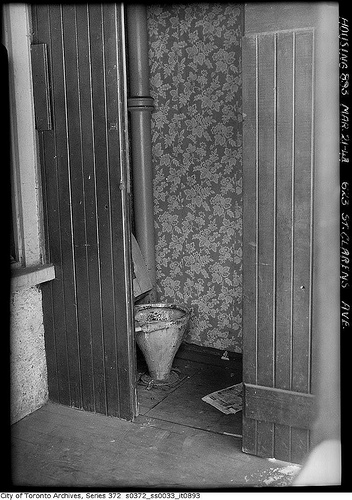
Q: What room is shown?
A: A bathroom.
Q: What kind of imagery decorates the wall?
A: Floral print.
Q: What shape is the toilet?
A: Conical.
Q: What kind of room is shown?
A: A bathroom.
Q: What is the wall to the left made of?
A: Wood.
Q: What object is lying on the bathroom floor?
A: A piece of paper.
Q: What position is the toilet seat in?
A: It is up.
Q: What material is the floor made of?
A: Wood.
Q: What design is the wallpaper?
A: Floral.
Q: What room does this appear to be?
A: Bathroom.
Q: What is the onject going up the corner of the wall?
A: Pipe.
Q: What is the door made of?
A: Wood.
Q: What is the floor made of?
A: Wood.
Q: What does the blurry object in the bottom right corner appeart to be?
A: Finger or thumb.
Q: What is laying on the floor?
A: Piece of paper.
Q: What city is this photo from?
A: Toronto.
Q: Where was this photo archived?
A: Toronto.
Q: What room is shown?
A: Bathroom.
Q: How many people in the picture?
A: None.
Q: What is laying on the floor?
A: Newspaper.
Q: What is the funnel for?
A: Toilet.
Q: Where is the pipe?
A: In the corner.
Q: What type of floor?
A: Wood.